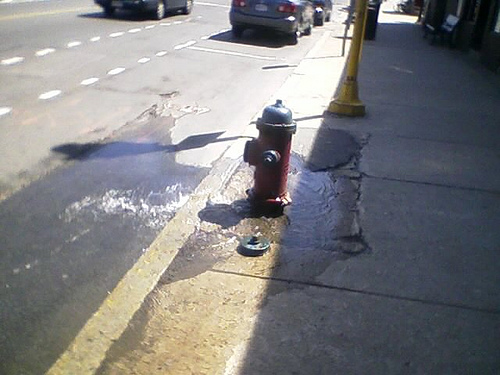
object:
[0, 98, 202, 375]
water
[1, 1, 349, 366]
road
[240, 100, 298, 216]
fire hydrant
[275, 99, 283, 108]
top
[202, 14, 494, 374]
sidewalk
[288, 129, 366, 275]
water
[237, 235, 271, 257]
cap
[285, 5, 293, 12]
light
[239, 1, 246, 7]
light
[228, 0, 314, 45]
car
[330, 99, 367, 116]
base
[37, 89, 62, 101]
line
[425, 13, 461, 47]
bench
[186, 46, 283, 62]
line